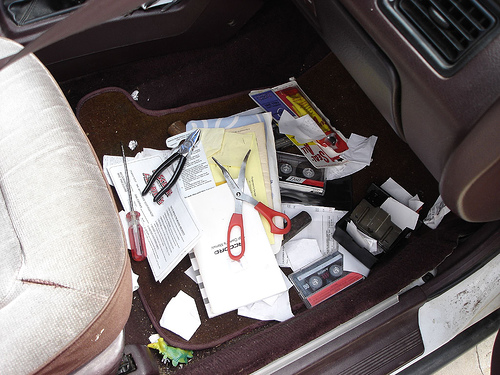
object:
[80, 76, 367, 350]
mat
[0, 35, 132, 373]
seat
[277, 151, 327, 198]
cassette tape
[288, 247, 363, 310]
cassette tape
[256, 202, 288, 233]
handle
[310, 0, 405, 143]
jockey box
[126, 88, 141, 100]
trash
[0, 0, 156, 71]
seat belt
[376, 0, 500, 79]
air conditioner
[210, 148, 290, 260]
scissors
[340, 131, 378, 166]
paper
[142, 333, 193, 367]
object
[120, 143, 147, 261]
screwdriver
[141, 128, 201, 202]
pliers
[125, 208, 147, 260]
handle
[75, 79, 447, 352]
carpet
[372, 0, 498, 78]
air vent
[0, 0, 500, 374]
car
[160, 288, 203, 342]
paper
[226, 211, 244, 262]
handle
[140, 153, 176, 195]
handle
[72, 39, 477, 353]
floorboard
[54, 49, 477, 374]
floor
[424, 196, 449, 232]
junk